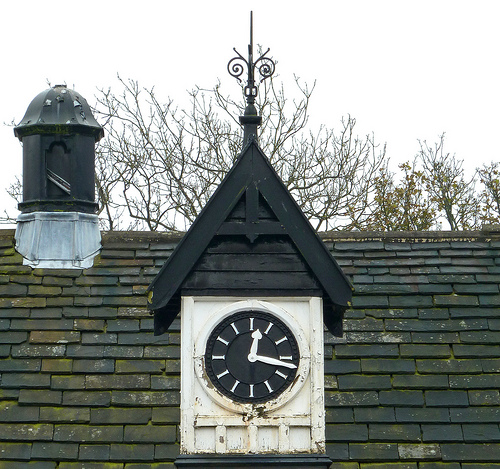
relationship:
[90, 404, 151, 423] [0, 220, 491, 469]
tile on rooftop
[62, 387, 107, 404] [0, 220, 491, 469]
tile on rooftop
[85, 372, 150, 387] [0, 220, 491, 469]
tile on rooftop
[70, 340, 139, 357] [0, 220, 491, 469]
tile on rooftop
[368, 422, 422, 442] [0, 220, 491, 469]
tile on rooftop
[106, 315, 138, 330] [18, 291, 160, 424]
tile on roof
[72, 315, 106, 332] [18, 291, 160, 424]
tile on roof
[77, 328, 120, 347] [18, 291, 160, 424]
tile on roof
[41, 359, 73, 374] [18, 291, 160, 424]
tile on roof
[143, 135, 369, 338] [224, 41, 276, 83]
black triangle with curlicue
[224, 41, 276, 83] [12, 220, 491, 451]
curlicue on rooftop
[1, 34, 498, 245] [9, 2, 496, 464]
branches behind roof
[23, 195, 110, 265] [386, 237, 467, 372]
cylinder on roofing tiles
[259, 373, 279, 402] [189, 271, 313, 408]
number on clock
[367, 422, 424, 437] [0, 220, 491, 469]
tile on rooftop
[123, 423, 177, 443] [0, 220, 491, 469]
tile on rooftop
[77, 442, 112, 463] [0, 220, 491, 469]
tile on rooftop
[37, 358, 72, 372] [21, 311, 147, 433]
tile on roof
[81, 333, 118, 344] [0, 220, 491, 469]
tile on rooftop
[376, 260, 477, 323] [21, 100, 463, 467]
tile of roof